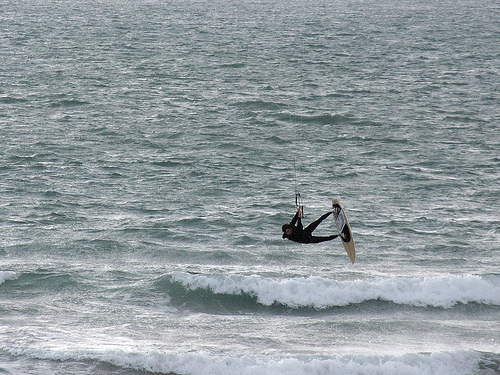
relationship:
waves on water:
[5, 175, 495, 370] [1, 2, 496, 369]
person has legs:
[281, 206, 348, 243] [308, 209, 340, 243]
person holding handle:
[281, 206, 348, 243] [294, 190, 306, 220]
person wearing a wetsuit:
[281, 206, 348, 243] [283, 215, 338, 244]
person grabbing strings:
[281, 206, 348, 243] [292, 117, 305, 219]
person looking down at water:
[281, 206, 348, 243] [1, 2, 496, 369]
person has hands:
[281, 206, 348, 243] [296, 207, 303, 221]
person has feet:
[281, 206, 348, 243] [331, 207, 347, 240]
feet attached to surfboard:
[331, 207, 347, 240] [331, 198, 357, 265]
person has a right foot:
[281, 206, 348, 243] [339, 231, 348, 240]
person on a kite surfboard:
[281, 206, 348, 243] [331, 198, 357, 265]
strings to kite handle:
[292, 117, 305, 219] [294, 190, 306, 220]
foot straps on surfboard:
[332, 207, 347, 241] [331, 198, 357, 265]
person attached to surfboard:
[281, 206, 348, 243] [331, 198, 357, 265]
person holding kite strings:
[281, 206, 348, 243] [292, 117, 305, 219]